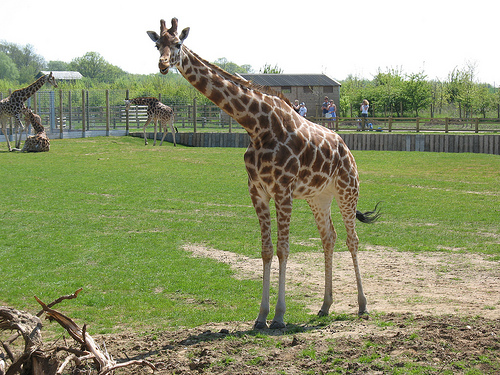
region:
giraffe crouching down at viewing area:
[122, 95, 179, 146]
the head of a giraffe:
[146, 18, 192, 77]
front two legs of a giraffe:
[245, 183, 290, 330]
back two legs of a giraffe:
[303, 191, 370, 320]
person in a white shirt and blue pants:
[359, 98, 371, 130]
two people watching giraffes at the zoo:
[319, 95, 337, 125]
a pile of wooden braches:
[0, 288, 163, 373]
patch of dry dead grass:
[178, 238, 498, 323]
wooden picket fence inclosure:
[130, 132, 497, 154]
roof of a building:
[33, 70, 83, 82]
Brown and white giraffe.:
[146, 17, 388, 332]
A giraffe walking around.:
[122, 93, 181, 148]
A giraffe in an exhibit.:
[0, 71, 59, 153]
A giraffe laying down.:
[11, 105, 51, 155]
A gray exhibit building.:
[240, 72, 343, 117]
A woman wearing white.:
[356, 98, 373, 116]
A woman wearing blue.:
[325, 98, 336, 128]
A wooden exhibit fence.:
[304, 115, 499, 154]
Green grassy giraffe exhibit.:
[1, 133, 499, 374]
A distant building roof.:
[34, 68, 84, 83]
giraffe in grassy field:
[111, 93, 198, 149]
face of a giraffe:
[20, 65, 70, 95]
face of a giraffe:
[125, 0, 192, 80]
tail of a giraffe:
[351, 196, 386, 232]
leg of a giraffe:
[336, 186, 371, 327]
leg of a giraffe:
[308, 196, 338, 317]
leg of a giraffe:
[270, 190, 312, 336]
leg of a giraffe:
[245, 183, 272, 323]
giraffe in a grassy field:
[145, 10, 400, 340]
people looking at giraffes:
[320, 94, 375, 128]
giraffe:
[129, 23, 399, 338]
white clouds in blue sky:
[408, 6, 493, 106]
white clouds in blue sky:
[370, 32, 427, 57]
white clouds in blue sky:
[343, 19, 420, 66]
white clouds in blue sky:
[287, 25, 351, 48]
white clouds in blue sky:
[245, 17, 322, 70]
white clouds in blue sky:
[60, 8, 113, 63]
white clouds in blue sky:
[287, 2, 377, 72]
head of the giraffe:
[136, 15, 198, 82]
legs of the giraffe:
[205, 209, 389, 362]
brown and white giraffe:
[256, 125, 346, 184]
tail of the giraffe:
[353, 188, 398, 235]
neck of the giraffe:
[180, 47, 268, 130]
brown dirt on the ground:
[398, 260, 470, 312]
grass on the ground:
[83, 233, 190, 329]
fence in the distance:
[385, 108, 458, 160]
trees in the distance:
[380, 49, 472, 111]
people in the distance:
[306, 87, 391, 134]